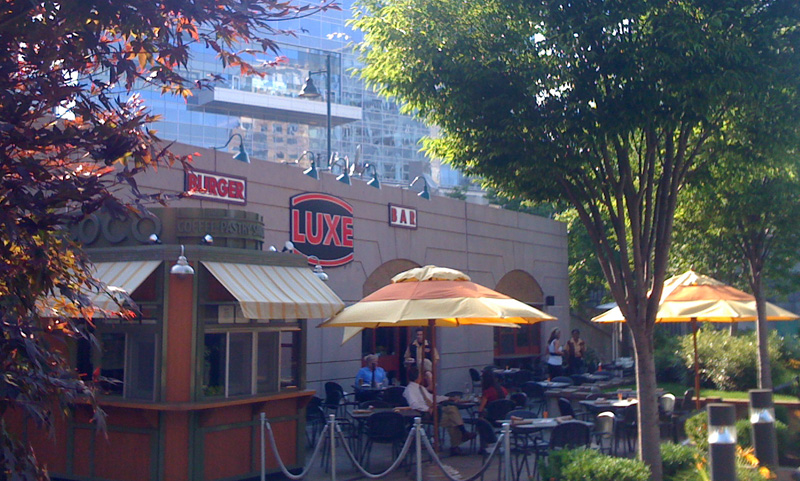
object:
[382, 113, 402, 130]
window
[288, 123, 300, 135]
window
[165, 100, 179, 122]
window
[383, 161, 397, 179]
window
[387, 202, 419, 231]
sign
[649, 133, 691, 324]
branches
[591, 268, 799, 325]
umbrella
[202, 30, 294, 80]
leaves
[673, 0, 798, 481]
tree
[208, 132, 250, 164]
green light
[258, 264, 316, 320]
stripes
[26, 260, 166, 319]
awnings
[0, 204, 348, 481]
small building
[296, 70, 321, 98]
light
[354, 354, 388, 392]
people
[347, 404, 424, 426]
table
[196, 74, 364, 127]
window washing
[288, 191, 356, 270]
luxe sign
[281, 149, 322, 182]
lights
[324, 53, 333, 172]
light pole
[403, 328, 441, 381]
waiter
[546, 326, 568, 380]
people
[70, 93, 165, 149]
red leaves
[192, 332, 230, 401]
window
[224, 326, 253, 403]
window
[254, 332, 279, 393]
window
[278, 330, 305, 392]
window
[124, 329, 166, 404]
window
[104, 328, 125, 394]
window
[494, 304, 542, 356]
window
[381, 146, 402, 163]
window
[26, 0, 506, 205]
building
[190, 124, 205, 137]
window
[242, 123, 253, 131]
window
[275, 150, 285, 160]
window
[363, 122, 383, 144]
window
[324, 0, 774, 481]
tree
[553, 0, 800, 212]
part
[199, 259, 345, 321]
awning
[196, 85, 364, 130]
platform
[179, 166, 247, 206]
sign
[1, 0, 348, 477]
tree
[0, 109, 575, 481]
building